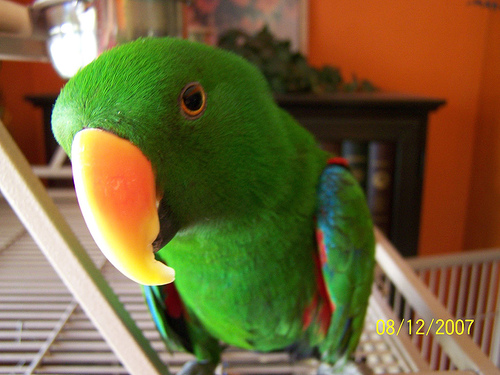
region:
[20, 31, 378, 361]
stuffed colorful bird on white rails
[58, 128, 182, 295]
yellow beak on bird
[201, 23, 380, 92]
plant on the shelf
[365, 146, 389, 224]
book in a row of several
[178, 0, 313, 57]
picture on the wall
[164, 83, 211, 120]
button eye of bird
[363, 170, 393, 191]
symbol on end of book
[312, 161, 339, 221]
blue patch on bird's feather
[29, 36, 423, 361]
The parrot is the color green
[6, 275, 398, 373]
The rack is the color white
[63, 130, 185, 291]
The beak of the parrot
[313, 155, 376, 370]
The wing of the bird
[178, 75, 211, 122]
The eye of the bird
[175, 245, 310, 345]
The stomach of the bird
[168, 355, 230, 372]
The foot of the bird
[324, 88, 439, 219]
The book shelf is the color brown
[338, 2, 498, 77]
The back wall is the color orange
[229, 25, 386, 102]
The plant on top of the shelf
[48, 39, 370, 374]
colorful bird setting on top of cage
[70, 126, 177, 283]
long yellow curled under beak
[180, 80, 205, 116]
black eyes with yellow surrounding pupil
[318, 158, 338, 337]
red and blue vibrant coloring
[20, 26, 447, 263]
piece of dark brown wood furniture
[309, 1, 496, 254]
walls are painted bright orange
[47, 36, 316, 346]
soft velvet feathers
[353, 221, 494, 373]
birds birdcage that is opened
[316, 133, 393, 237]
books on dark colored bookshelf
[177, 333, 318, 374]
bird using feet to hold onto cage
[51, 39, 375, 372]
The parrot is mostly green.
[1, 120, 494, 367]
The bird is standing on a multi level white surface.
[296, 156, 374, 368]
The green wing has blue and red edging.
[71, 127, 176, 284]
The beak is large and yellow.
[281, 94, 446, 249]
Three books are on the bookshelf.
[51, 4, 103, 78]
A light is on behind the green surface.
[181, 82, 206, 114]
The eye is round, yellow with a black middle.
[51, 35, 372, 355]
The green parrot has some blue and red feathers.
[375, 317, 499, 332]
Date 08/12/2007 on white stripes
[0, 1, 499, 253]
The wall is orange behind the parrot.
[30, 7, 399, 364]
Green parrot staring at camera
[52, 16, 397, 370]
Green parrot with red and blue feathers in wings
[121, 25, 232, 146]
Parrot's black eye with yellow circle around it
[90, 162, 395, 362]
Parrot chest and wings resting on sides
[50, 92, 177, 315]
Parrot's bright yellow-orange beak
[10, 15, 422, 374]
Parrot standing in a bird cage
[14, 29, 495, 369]
Parrot in an open bird cage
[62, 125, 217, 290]
Parrot's beak and mouth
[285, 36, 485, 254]
Book case with bookcase in it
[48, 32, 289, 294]
Parrot's head and beak